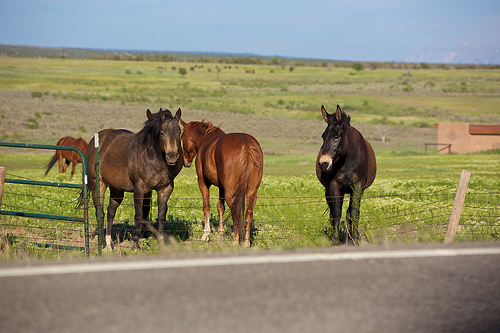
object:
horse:
[315, 102, 378, 245]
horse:
[176, 117, 264, 247]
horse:
[85, 105, 180, 257]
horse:
[46, 130, 88, 177]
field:
[0, 57, 497, 257]